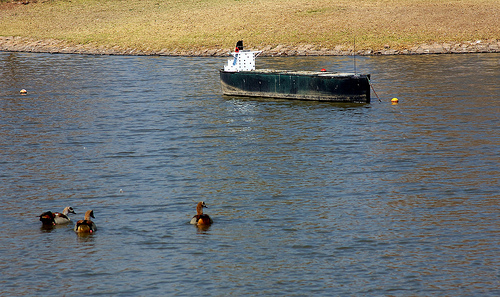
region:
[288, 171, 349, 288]
the water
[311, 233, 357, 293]
the water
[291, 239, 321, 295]
the water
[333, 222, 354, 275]
the water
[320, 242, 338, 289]
the water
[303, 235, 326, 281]
the water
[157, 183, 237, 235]
duck in the lake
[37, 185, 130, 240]
ducks in the lake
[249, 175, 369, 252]
blue waves on water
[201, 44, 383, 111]
boat in the distance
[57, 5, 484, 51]
grassy hill in back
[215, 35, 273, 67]
white portion of the boat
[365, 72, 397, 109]
string attached to boat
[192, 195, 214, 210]
head of the duck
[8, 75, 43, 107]
random floating item in water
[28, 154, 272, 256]
ducks floating in water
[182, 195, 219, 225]
a mallard duck in water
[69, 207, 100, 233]
a mallard duck in water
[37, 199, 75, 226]
a mallard duck in water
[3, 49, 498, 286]
a large body of water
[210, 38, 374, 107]
a remote control tanker boat toy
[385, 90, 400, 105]
a yellow and orange buoy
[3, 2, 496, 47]
a dry grassy area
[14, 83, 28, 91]
a yellow and orange buoy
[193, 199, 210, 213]
a duck's head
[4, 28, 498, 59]
a rocky water border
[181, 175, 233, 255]
duck in the water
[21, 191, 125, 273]
two ducks swimming in the water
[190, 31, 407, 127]
a small boat in the water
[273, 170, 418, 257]
calm blue water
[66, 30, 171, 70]
rocky shore of the water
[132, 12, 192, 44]
dead grass on the beach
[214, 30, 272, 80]
white cover on the boat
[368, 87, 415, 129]
orange flotation device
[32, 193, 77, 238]
gray duck looking for food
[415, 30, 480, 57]
rocks by the water